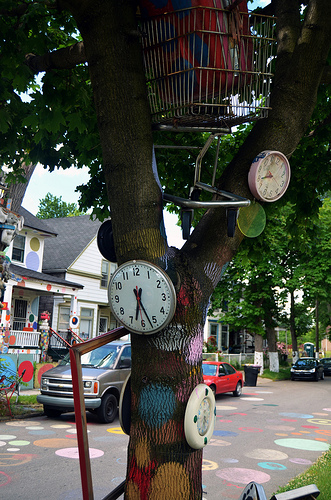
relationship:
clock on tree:
[102, 259, 173, 329] [129, 182, 212, 287]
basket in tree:
[136, 12, 236, 154] [129, 182, 212, 287]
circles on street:
[246, 428, 306, 483] [227, 402, 298, 438]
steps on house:
[50, 332, 82, 367] [14, 225, 53, 341]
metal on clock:
[252, 166, 262, 206] [257, 143, 299, 228]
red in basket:
[206, 23, 240, 83] [136, 12, 236, 154]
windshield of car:
[202, 363, 224, 380] [208, 354, 237, 407]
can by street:
[241, 351, 261, 385] [227, 402, 298, 438]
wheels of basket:
[175, 210, 257, 234] [136, 12, 236, 154]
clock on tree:
[176, 375, 228, 445] [129, 182, 212, 287]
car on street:
[208, 354, 237, 407] [227, 402, 298, 438]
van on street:
[82, 339, 136, 431] [227, 402, 298, 438]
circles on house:
[26, 234, 45, 272] [14, 225, 53, 341]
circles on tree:
[126, 241, 240, 494] [129, 182, 212, 287]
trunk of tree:
[140, 336, 183, 394] [129, 182, 212, 287]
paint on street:
[10, 415, 94, 454] [227, 402, 298, 438]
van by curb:
[82, 339, 136, 431] [3, 415, 46, 421]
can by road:
[241, 351, 261, 385] [250, 383, 283, 400]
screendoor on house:
[99, 312, 115, 348] [63, 220, 106, 317]